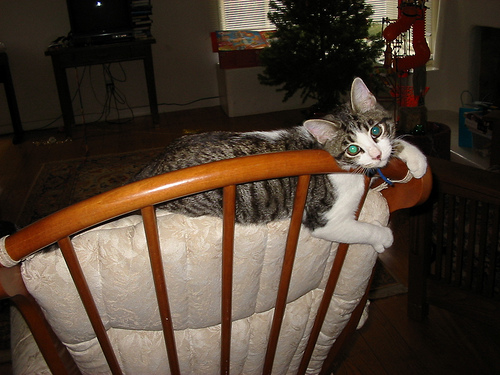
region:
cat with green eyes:
[73, 78, 424, 249]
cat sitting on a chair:
[97, 74, 436, 254]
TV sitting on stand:
[62, 0, 164, 35]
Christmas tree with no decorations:
[277, 3, 398, 95]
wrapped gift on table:
[207, 22, 272, 52]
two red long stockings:
[386, 2, 443, 71]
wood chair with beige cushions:
[21, 125, 418, 371]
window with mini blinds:
[224, 0, 437, 44]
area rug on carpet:
[40, 137, 445, 207]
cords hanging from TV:
[77, 60, 145, 120]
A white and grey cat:
[113, 100, 428, 237]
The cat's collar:
[353, 131, 412, 193]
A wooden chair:
[18, 130, 415, 373]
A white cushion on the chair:
[28, 241, 374, 373]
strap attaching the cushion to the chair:
[0, 189, 63, 285]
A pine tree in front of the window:
[260, 0, 390, 130]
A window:
[215, 0, 442, 41]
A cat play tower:
[372, 5, 462, 168]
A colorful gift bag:
[207, 20, 277, 61]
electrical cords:
[88, 75, 221, 114]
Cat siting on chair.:
[132, 102, 429, 252]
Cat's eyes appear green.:
[342, 120, 389, 162]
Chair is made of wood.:
[22, 130, 438, 372]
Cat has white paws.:
[305, 127, 445, 256]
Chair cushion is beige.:
[14, 211, 389, 363]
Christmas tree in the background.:
[257, 0, 423, 130]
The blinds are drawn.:
[168, 0, 444, 62]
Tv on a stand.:
[2, 4, 180, 128]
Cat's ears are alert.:
[301, 73, 380, 152]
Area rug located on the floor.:
[23, 137, 411, 308]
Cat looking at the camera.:
[314, 82, 409, 182]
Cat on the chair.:
[148, 76, 435, 251]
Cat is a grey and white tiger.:
[126, 82, 414, 247]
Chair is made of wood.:
[0, 133, 413, 373]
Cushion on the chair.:
[91, 240, 321, 373]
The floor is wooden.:
[364, 315, 459, 369]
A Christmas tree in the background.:
[283, 10, 362, 97]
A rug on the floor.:
[56, 157, 141, 191]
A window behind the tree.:
[223, 0, 275, 31]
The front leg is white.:
[331, 217, 400, 250]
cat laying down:
[119, 124, 446, 234]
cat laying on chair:
[136, 112, 458, 302]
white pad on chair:
[98, 234, 370, 329]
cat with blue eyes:
[322, 107, 410, 186]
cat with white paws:
[311, 162, 447, 252]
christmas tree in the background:
[260, 5, 363, 98]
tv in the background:
[58, 6, 217, 58]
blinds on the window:
[220, 1, 280, 25]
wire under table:
[79, 75, 144, 131]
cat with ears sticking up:
[305, 97, 422, 162]